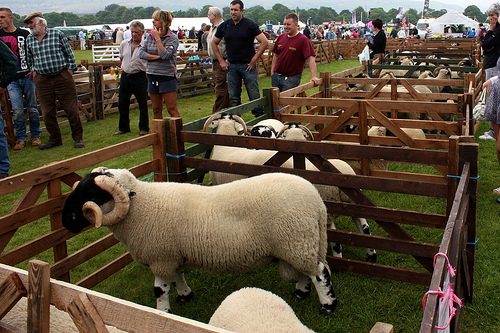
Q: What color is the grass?
A: Green.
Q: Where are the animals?
A: In pens.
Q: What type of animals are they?
A: Rams.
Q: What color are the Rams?
A: White.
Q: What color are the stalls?
A: Brown.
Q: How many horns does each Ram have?
A: Two.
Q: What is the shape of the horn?
A: Spiral.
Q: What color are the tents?
A: White.